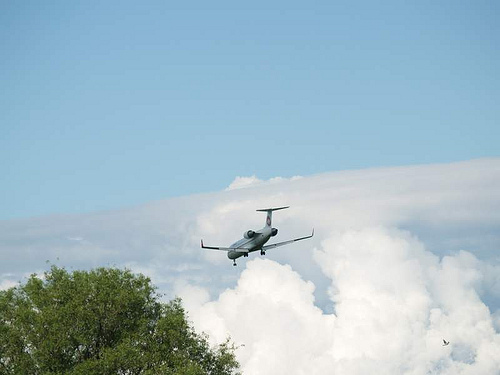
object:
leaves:
[106, 337, 122, 352]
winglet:
[200, 238, 251, 252]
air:
[0, 0, 499, 157]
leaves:
[57, 256, 60, 260]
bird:
[440, 338, 450, 346]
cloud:
[0, 155, 499, 374]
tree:
[1, 255, 244, 373]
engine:
[242, 228, 256, 237]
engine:
[271, 226, 279, 235]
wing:
[264, 227, 315, 249]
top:
[0, 257, 172, 320]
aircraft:
[201, 206, 315, 265]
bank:
[0, 156, 499, 300]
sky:
[0, 0, 499, 373]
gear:
[232, 262, 237, 266]